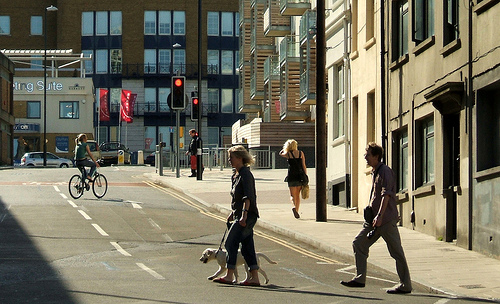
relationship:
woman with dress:
[280, 138, 309, 219] [285, 149, 309, 180]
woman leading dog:
[213, 144, 259, 285] [200, 249, 275, 283]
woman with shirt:
[74, 134, 99, 193] [75, 142, 89, 160]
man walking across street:
[339, 142, 411, 295] [1, 167, 461, 303]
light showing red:
[171, 76, 185, 110] [175, 79, 183, 86]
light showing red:
[191, 96, 200, 119] [193, 97, 199, 105]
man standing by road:
[187, 128, 199, 178] [1, 167, 461, 303]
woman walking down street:
[213, 144, 259, 285] [1, 167, 461, 303]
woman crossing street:
[213, 144, 259, 285] [1, 167, 461, 303]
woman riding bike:
[74, 134, 99, 193] [69, 157, 108, 200]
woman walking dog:
[213, 144, 259, 285] [200, 249, 275, 283]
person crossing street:
[339, 142, 411, 295] [1, 167, 461, 303]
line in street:
[54, 186, 165, 280] [1, 167, 461, 303]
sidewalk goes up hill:
[145, 170, 497, 301] [0, 164, 499, 301]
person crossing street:
[213, 144, 259, 285] [1, 167, 461, 303]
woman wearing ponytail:
[74, 134, 99, 193] [74, 136, 80, 145]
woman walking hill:
[280, 138, 309, 219] [0, 164, 499, 301]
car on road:
[21, 152, 72, 167] [1, 167, 461, 303]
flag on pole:
[120, 90, 131, 123] [116, 89, 123, 149]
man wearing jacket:
[187, 128, 199, 178] [188, 136, 200, 153]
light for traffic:
[171, 76, 185, 110] [22, 132, 109, 199]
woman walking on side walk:
[280, 138, 309, 219] [145, 170, 497, 301]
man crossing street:
[339, 142, 411, 295] [1, 167, 461, 303]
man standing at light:
[187, 128, 199, 178] [191, 96, 200, 119]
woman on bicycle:
[74, 134, 99, 193] [69, 157, 108, 200]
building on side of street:
[232, 2, 315, 168] [1, 167, 461, 303]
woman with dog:
[213, 144, 259, 285] [200, 249, 275, 283]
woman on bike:
[74, 134, 99, 193] [69, 157, 108, 200]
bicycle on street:
[69, 157, 108, 200] [1, 167, 461, 303]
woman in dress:
[280, 138, 309, 219] [285, 149, 309, 180]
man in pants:
[187, 128, 199, 178] [190, 151, 200, 172]